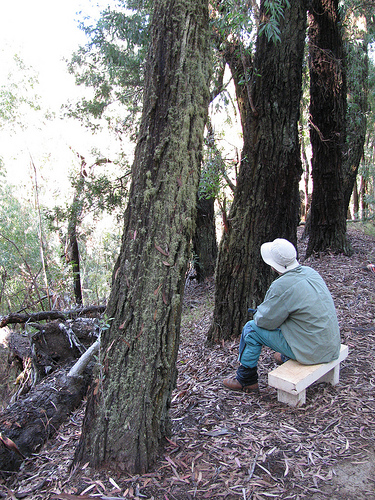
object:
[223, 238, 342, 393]
person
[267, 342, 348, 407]
bench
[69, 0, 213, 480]
tree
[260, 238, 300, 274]
hat